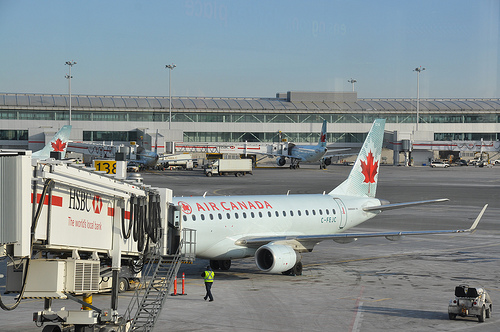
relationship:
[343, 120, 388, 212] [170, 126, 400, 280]
tail of plane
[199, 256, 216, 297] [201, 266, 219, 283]
man wearing vest